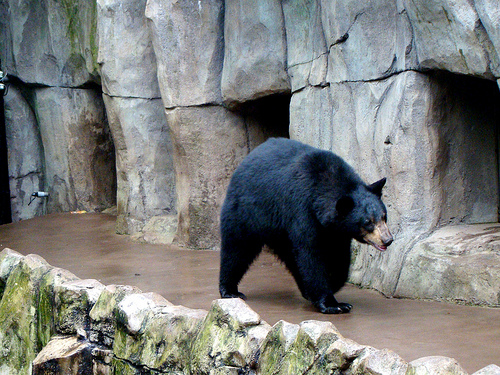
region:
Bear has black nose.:
[378, 233, 401, 252]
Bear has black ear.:
[373, 173, 393, 199]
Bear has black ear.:
[326, 190, 361, 226]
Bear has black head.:
[342, 188, 378, 230]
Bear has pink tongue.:
[376, 239, 393, 258]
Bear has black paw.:
[311, 266, 366, 334]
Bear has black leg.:
[295, 231, 324, 277]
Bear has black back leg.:
[198, 235, 258, 307]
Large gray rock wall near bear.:
[218, 312, 276, 358]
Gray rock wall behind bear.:
[305, 72, 442, 164]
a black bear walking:
[193, 123, 414, 310]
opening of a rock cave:
[414, 71, 498, 246]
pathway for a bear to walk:
[400, 303, 479, 360]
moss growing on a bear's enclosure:
[129, 319, 229, 367]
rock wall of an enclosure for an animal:
[30, 68, 209, 223]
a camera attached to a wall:
[25, 185, 50, 208]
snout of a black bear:
[367, 223, 396, 251]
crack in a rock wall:
[280, 20, 390, 75]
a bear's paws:
[305, 291, 365, 322]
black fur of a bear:
[260, 167, 307, 212]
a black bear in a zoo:
[195, 127, 411, 325]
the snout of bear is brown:
[367, 215, 397, 255]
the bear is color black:
[206, 125, 408, 327]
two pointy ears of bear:
[334, 173, 391, 203]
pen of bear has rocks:
[6, 6, 499, 367]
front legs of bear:
[286, 264, 365, 320]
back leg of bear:
[213, 240, 258, 302]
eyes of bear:
[361, 210, 391, 225]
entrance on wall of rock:
[409, 60, 499, 270]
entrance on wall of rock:
[66, 78, 132, 218]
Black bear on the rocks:
[201, 108, 428, 313]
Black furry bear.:
[170, 106, 484, 369]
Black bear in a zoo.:
[200, 105, 420, 325]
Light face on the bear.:
[320, 165, 425, 281]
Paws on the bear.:
[208, 277, 367, 335]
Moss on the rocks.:
[31, 279, 116, 361]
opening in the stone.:
[233, 83, 320, 158]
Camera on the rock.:
[23, 177, 83, 225]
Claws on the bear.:
[329, 298, 371, 325]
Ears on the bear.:
[316, 161, 413, 231]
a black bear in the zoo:
[217, 135, 394, 312]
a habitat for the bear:
[2, 3, 497, 373]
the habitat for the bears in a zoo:
[21, 23, 480, 354]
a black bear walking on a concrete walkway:
[131, 135, 450, 315]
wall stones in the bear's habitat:
[1, 1, 498, 306]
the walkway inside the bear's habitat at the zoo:
[3, 210, 498, 373]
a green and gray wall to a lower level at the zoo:
[0, 245, 499, 372]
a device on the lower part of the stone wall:
[28, 188, 48, 205]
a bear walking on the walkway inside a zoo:
[216, 134, 394, 314]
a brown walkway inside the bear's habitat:
[0, 210, 498, 373]